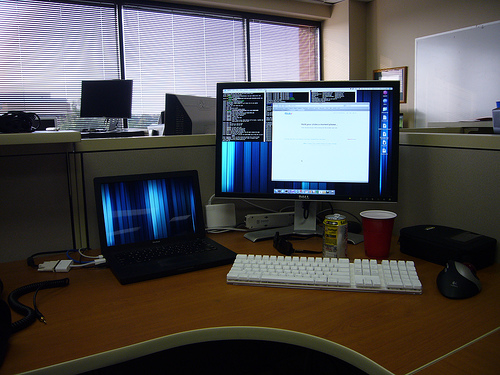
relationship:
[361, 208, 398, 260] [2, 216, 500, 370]
cup on desk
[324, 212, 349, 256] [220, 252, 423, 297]
can behind keyboard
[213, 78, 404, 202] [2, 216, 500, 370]
monitor on desk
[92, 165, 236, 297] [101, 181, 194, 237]
laptop with lines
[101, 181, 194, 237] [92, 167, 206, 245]
lines on screen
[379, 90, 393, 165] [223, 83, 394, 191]
icons on screen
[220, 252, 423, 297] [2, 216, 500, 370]
keyboard on desk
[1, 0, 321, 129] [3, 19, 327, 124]
blinds on window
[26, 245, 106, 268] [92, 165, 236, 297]
cables in laptop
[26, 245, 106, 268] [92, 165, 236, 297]
cables plugged into laptop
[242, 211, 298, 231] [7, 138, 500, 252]
strip next to wall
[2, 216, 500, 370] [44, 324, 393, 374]
desk has edge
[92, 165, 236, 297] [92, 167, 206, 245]
laptop with screen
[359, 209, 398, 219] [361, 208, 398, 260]
trim inside cup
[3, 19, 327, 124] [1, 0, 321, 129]
window with blinds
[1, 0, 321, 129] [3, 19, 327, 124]
blinds over window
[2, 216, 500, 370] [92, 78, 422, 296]
desk with computers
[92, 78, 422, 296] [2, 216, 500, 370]
computers on desk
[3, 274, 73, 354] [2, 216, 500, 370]
cords on desk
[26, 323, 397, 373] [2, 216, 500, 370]
curve on desk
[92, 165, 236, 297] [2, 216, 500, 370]
laptop on desk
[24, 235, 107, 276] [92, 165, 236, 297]
wires into laptop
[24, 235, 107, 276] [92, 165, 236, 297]
wires plugged into laptop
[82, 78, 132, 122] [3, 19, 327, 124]
screen in front of window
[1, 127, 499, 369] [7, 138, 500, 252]
cubicle has wall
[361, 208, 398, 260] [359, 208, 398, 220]
cup with trim